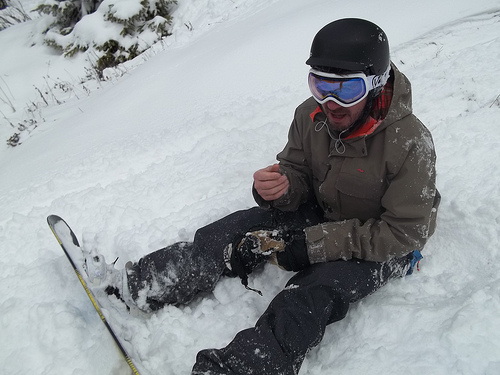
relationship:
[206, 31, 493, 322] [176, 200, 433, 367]
man wearing pants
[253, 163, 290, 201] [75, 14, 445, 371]
fingers of person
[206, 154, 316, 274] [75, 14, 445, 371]
hand of person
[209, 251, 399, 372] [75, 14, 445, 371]
leg of person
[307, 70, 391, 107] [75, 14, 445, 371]
goggle of person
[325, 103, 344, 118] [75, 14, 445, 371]
nose of person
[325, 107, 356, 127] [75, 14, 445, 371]
mouth of person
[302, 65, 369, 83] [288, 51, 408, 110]
lining on goggles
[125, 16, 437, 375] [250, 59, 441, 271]
man wears hoody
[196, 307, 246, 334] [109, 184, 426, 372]
snow on pants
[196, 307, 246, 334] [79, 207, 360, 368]
snow between legs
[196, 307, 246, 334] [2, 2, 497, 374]
snow on ground